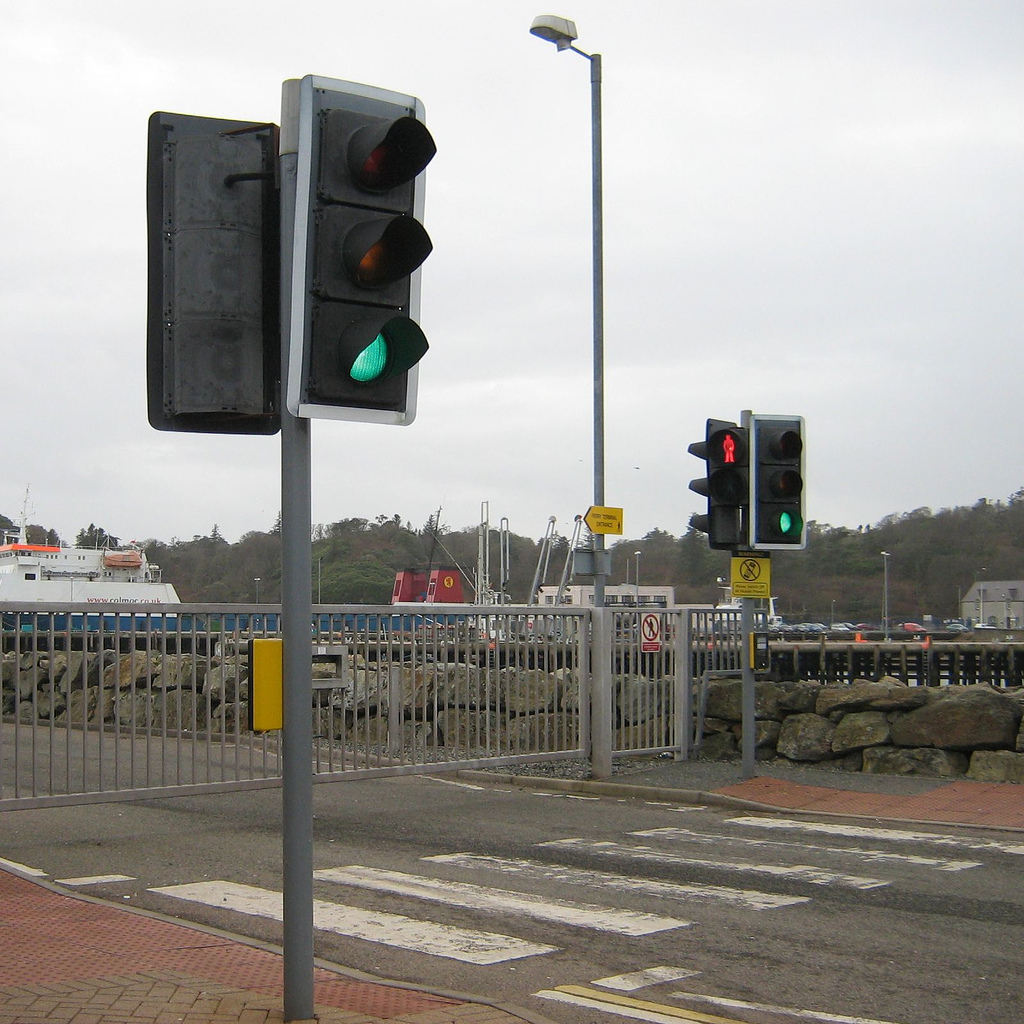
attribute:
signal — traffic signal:
[269, 70, 459, 426]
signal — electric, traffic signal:
[151, 67, 423, 435]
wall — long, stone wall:
[8, 646, 1008, 761]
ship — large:
[0, 534, 188, 611]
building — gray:
[960, 580, 1018, 631]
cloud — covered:
[522, 156, 985, 378]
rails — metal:
[8, 614, 761, 783]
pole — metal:
[278, 79, 321, 1013]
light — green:
[277, 68, 430, 436]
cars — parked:
[721, 613, 990, 634]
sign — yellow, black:
[726, 545, 774, 606]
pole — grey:
[277, 77, 329, 1019]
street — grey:
[69, 782, 1022, 944]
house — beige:
[960, 572, 1019, 623]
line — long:
[639, 819, 963, 870]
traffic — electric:
[224, 39, 499, 474]